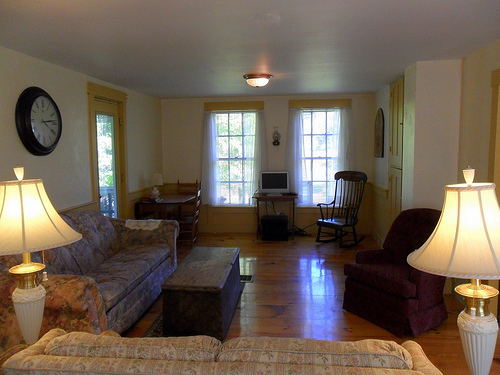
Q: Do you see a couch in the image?
A: Yes, there is a couch.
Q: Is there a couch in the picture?
A: Yes, there is a couch.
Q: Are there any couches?
A: Yes, there is a couch.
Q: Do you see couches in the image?
A: Yes, there is a couch.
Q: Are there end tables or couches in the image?
A: Yes, there is a couch.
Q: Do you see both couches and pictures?
A: No, there is a couch but no pictures.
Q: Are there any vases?
A: No, there are no vases.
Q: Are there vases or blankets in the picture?
A: No, there are no vases or blankets.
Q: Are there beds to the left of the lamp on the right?
A: No, there is a couch to the left of the lamp.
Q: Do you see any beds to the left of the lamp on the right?
A: No, there is a couch to the left of the lamp.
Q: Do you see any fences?
A: No, there are no fences.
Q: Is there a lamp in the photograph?
A: Yes, there is a lamp.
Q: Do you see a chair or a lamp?
A: Yes, there is a lamp.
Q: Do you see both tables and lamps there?
A: Yes, there are both a lamp and a table.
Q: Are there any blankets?
A: No, there are no blankets.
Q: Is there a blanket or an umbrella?
A: No, there are no blankets or umbrellas.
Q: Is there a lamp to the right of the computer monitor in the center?
A: Yes, there is a lamp to the right of the computer monitor.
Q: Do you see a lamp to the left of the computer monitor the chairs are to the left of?
A: No, the lamp is to the right of the computer monitor.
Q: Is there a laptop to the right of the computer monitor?
A: No, there is a lamp to the right of the computer monitor.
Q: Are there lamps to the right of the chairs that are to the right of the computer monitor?
A: Yes, there is a lamp to the right of the chairs.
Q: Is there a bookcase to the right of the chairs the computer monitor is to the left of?
A: No, there is a lamp to the right of the chairs.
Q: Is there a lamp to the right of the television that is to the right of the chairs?
A: Yes, there is a lamp to the right of the TV.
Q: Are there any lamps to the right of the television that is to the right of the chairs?
A: Yes, there is a lamp to the right of the TV.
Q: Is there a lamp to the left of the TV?
A: No, the lamp is to the right of the TV.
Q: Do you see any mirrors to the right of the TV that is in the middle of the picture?
A: No, there is a lamp to the right of the TV.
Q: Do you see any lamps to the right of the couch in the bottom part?
A: Yes, there is a lamp to the right of the couch.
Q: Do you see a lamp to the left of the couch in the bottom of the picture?
A: No, the lamp is to the right of the couch.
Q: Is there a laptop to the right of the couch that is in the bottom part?
A: No, there is a lamp to the right of the couch.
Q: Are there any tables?
A: Yes, there is a table.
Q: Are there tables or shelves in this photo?
A: Yes, there is a table.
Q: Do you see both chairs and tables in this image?
A: Yes, there are both a table and a chair.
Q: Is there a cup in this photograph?
A: No, there are no cups.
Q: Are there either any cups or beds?
A: No, there are no cups or beds.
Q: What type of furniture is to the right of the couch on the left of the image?
A: The piece of furniture is a table.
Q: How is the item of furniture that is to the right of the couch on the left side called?
A: The piece of furniture is a table.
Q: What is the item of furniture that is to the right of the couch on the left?
A: The piece of furniture is a table.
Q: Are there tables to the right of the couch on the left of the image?
A: Yes, there is a table to the right of the couch.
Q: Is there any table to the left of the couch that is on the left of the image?
A: No, the table is to the right of the couch.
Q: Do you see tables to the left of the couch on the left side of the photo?
A: No, the table is to the right of the couch.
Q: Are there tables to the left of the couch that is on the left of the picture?
A: No, the table is to the right of the couch.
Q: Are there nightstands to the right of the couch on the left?
A: No, there is a table to the right of the couch.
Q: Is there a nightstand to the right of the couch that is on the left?
A: No, there is a table to the right of the couch.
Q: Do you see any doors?
A: Yes, there is a door.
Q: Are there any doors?
A: Yes, there is a door.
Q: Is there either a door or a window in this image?
A: Yes, there is a door.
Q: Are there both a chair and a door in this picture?
A: Yes, there are both a door and a chair.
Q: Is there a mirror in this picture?
A: No, there are no mirrors.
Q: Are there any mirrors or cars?
A: No, there are no mirrors or cars.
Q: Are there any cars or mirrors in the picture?
A: No, there are no mirrors or cars.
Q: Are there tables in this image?
A: Yes, there is a table.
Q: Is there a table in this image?
A: Yes, there is a table.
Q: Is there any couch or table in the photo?
A: Yes, there is a table.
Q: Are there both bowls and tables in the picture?
A: No, there is a table but no bowls.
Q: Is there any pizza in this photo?
A: No, there are no pizzas.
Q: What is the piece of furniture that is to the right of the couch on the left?
A: The piece of furniture is a table.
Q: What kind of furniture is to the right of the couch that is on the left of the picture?
A: The piece of furniture is a table.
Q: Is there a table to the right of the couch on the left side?
A: Yes, there is a table to the right of the couch.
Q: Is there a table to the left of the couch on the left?
A: No, the table is to the right of the couch.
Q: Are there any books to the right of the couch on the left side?
A: No, there is a table to the right of the couch.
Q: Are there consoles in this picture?
A: No, there are no consoles.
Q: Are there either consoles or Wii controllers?
A: No, there are no consoles or Wii controllers.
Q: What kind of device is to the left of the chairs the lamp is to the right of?
A: The device is a computer monitor.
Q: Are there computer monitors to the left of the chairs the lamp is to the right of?
A: Yes, there is a computer monitor to the left of the chairs.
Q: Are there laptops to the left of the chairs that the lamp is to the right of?
A: No, there is a computer monitor to the left of the chairs.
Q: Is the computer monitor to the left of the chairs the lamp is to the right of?
A: Yes, the computer monitor is to the left of the chairs.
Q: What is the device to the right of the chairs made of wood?
A: The device is a computer monitor.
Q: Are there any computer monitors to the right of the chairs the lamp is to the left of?
A: Yes, there is a computer monitor to the right of the chairs.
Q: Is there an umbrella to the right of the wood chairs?
A: No, there is a computer monitor to the right of the chairs.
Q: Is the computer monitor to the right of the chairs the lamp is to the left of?
A: Yes, the computer monitor is to the right of the chairs.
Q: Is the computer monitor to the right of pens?
A: No, the computer monitor is to the right of the chairs.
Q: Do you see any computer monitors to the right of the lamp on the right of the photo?
A: No, the computer monitor is to the left of the lamp.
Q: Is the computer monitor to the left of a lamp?
A: Yes, the computer monitor is to the left of a lamp.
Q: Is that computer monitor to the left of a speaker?
A: No, the computer monitor is to the left of a lamp.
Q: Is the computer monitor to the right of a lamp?
A: No, the computer monitor is to the left of a lamp.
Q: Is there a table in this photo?
A: Yes, there is a table.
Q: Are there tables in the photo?
A: Yes, there is a table.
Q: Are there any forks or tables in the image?
A: Yes, there is a table.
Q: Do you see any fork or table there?
A: Yes, there is a table.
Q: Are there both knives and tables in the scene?
A: No, there is a table but no knives.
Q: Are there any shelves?
A: No, there are no shelves.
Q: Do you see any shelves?
A: No, there are no shelves.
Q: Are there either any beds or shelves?
A: No, there are no shelves or beds.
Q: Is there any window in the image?
A: Yes, there is a window.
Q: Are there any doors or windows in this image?
A: Yes, there is a window.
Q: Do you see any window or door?
A: Yes, there is a window.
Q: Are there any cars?
A: No, there are no cars.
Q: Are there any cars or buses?
A: No, there are no cars or buses.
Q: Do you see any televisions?
A: Yes, there is a television.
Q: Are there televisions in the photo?
A: Yes, there is a television.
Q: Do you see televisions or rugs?
A: Yes, there is a television.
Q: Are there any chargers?
A: No, there are no chargers.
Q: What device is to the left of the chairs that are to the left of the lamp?
A: The device is a television.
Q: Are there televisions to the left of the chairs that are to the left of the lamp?
A: Yes, there is a television to the left of the chairs.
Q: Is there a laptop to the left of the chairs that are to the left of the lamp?
A: No, there is a television to the left of the chairs.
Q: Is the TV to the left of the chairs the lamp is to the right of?
A: Yes, the TV is to the left of the chairs.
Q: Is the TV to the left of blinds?
A: No, the TV is to the left of the chairs.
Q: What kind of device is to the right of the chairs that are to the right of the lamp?
A: The device is a television.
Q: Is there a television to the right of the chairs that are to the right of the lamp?
A: Yes, there is a television to the right of the chairs.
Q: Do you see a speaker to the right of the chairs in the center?
A: No, there is a television to the right of the chairs.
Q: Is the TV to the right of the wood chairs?
A: Yes, the TV is to the right of the chairs.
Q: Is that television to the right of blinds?
A: No, the television is to the right of the chairs.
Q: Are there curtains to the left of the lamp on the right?
A: No, there is a television to the left of the lamp.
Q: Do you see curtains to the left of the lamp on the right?
A: No, there is a television to the left of the lamp.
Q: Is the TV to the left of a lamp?
A: Yes, the TV is to the left of a lamp.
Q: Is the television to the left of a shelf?
A: No, the television is to the left of a lamp.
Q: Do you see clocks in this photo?
A: Yes, there is a clock.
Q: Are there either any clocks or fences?
A: Yes, there is a clock.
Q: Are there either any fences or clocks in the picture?
A: Yes, there is a clock.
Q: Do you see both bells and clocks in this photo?
A: No, there is a clock but no bells.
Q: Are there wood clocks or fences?
A: Yes, there is a wood clock.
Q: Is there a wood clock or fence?
A: Yes, there is a wood clock.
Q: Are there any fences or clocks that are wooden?
A: Yes, the clock is wooden.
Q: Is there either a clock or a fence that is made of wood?
A: Yes, the clock is made of wood.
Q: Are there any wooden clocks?
A: Yes, there is a wood clock.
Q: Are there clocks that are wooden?
A: Yes, there is a clock that is wooden.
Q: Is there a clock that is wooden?
A: Yes, there is a clock that is wooden.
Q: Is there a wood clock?
A: Yes, there is a clock that is made of wood.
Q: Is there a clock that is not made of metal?
A: Yes, there is a clock that is made of wood.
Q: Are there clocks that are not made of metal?
A: Yes, there is a clock that is made of wood.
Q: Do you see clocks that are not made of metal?
A: Yes, there is a clock that is made of wood.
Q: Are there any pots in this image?
A: No, there are no pots.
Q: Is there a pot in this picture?
A: No, there are no pots.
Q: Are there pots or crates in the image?
A: No, there are no pots or crates.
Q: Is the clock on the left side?
A: Yes, the clock is on the left of the image.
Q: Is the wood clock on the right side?
A: No, the clock is on the left of the image.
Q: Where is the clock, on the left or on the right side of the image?
A: The clock is on the left of the image.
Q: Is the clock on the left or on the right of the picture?
A: The clock is on the left of the image.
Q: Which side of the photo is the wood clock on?
A: The clock is on the left of the image.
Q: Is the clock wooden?
A: Yes, the clock is wooden.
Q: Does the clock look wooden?
A: Yes, the clock is wooden.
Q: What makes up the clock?
A: The clock is made of wood.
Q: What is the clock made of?
A: The clock is made of wood.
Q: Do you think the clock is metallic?
A: No, the clock is wooden.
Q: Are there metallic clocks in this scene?
A: No, there is a clock but it is wooden.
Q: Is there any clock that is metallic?
A: No, there is a clock but it is wooden.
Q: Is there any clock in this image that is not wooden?
A: No, there is a clock but it is wooden.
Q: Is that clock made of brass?
A: No, the clock is made of wood.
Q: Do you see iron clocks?
A: No, there is a clock but it is made of wood.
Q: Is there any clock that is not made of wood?
A: No, there is a clock but it is made of wood.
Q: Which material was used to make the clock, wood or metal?
A: The clock is made of wood.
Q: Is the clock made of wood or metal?
A: The clock is made of wood.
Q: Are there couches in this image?
A: Yes, there is a couch.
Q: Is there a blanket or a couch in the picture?
A: Yes, there is a couch.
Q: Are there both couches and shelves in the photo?
A: No, there is a couch but no shelves.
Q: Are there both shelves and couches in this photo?
A: No, there is a couch but no shelves.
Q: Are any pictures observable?
A: No, there are no pictures.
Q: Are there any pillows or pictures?
A: No, there are no pictures or pillows.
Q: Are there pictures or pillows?
A: No, there are no pictures or pillows.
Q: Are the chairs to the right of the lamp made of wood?
A: Yes, the chairs are made of wood.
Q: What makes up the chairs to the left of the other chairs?
A: The chairs are made of wood.